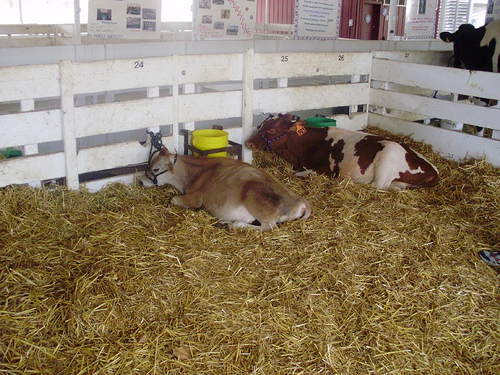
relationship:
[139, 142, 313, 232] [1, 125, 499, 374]
cow on hay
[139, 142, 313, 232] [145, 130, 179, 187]
cow wearing a harness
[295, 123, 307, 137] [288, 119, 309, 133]
tag on cow's ear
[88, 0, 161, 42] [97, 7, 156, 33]
poster has pictures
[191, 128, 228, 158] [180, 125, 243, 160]
bucket in a frame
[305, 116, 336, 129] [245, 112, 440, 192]
bucket near cow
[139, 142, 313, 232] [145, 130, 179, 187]
cow has a harness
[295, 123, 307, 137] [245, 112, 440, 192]
tag on cow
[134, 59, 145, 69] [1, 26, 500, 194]
24 on fence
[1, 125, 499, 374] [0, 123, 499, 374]
hay on ground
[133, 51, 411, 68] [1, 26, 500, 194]
numbers on fence